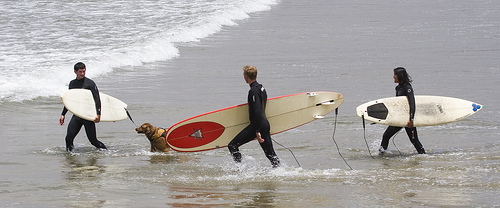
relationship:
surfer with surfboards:
[59, 61, 107, 151] [61, 90, 484, 155]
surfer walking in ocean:
[59, 61, 107, 151] [0, 0, 500, 208]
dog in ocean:
[135, 123, 172, 152] [0, 0, 500, 208]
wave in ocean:
[0, 0, 278, 101] [0, 0, 500, 208]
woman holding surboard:
[377, 67, 426, 154] [355, 97, 482, 128]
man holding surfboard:
[228, 66, 280, 167] [163, 91, 344, 152]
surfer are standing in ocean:
[59, 61, 107, 151] [0, 0, 500, 208]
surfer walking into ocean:
[59, 61, 107, 151] [0, 2, 159, 177]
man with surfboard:
[228, 66, 280, 167] [163, 91, 344, 152]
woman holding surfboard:
[377, 67, 426, 154] [354, 96, 484, 127]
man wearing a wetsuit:
[228, 66, 280, 167] [230, 79, 280, 165]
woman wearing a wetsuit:
[377, 67, 426, 154] [378, 83, 426, 153]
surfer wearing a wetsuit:
[59, 61, 107, 151] [63, 78, 106, 150]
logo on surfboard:
[188, 128, 204, 140] [163, 91, 344, 152]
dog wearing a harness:
[135, 123, 172, 152] [150, 126, 166, 141]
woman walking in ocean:
[377, 67, 426, 154] [0, 0, 500, 208]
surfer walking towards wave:
[59, 61, 107, 151] [0, 0, 278, 101]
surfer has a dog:
[59, 63, 106, 150] [135, 123, 172, 152]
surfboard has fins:
[163, 91, 344, 152] [306, 93, 335, 119]